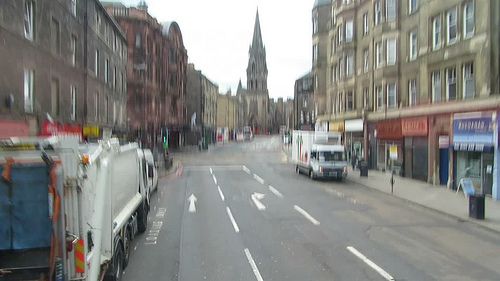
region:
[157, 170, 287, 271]
Two arrows on a road.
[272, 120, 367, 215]
Van on a road.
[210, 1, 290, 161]
Tall building with a point roof.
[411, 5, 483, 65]
Windows on a building.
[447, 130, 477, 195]
White sign in front of a building.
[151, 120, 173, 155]
Traffic light that is green.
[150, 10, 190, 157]
Building with a curved roof.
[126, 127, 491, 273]
Street with a vehicle on it.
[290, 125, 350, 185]
Van with its headlights on.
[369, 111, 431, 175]
Red sign on a building.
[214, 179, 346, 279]
broken lines in street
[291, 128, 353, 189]
white truck with red marking on side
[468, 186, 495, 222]
black wire trash bin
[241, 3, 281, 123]
tall gray building with spiral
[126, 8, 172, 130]
red building with windows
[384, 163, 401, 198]
black parking meter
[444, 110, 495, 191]
blue storefront with purple sign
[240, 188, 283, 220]
white direction marker in street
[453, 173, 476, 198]
blue sign with stand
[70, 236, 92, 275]
red and gold spiral on truck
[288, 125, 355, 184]
a white truck on the ride side of the road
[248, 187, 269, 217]
a white arrow pointing right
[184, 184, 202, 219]
a white arrow pointing straight ahead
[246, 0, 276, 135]
a building that comes to a point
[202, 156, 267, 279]
chopped white lines on the road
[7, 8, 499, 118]
old buildings on both sides of the street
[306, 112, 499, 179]
a row of businesses along the street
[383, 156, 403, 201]
a parking meter on the curb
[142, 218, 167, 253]
the word loading in white letters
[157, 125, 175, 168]
a green stop light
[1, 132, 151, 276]
Garbage truck on side of street.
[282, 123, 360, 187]
Truck parked on side of street.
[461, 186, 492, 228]
Trash bin on sidewalk.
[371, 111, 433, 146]
Store with red sign out front.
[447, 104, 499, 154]
Store with blue sign out front.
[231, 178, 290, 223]
A white turning arrow.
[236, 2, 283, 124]
Building with spire on top.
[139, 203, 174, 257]
White writing on street.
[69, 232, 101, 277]
Yellow and orange reflector on truck.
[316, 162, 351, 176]
Headlights on front of truck.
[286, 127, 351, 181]
Stopped white car on the street.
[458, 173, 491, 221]
Black trash can.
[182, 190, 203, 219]
White arrow on the road.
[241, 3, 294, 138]
Old church in the city.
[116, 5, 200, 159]
Red building with four floors.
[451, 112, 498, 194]
Painted blue store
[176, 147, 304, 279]
Road in the city.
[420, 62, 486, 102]
Three windows of a building.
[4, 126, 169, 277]
Trash truck on the left of the street.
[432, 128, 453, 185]
Blue door of a building.